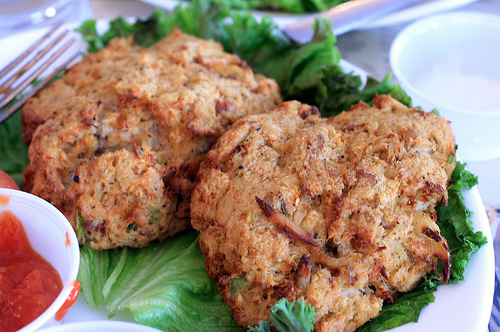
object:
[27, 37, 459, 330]
meal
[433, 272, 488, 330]
plate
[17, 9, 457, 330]
food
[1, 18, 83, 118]
fork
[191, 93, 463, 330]
cake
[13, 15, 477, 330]
lettuce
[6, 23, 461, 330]
bib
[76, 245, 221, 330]
lettuce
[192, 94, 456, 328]
crabcake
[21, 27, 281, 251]
crabcake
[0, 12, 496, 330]
plate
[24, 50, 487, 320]
plate